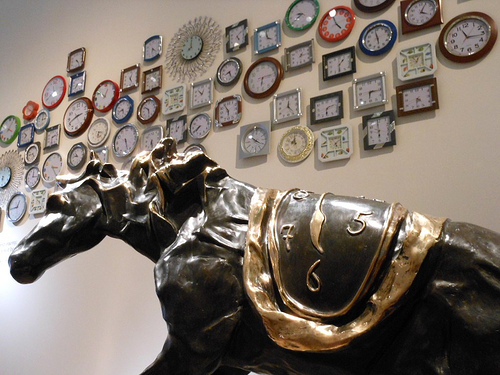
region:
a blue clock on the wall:
[355, 15, 396, 66]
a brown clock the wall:
[437, 5, 499, 79]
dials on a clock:
[67, 112, 84, 123]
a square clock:
[58, 41, 92, 73]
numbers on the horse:
[238, 165, 442, 315]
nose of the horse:
[3, 228, 51, 289]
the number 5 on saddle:
[336, 202, 382, 257]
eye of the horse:
[42, 178, 70, 222]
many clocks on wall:
[31, 21, 266, 158]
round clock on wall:
[228, 49, 290, 110]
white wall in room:
[401, 132, 473, 202]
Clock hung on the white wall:
[358, 108, 397, 149]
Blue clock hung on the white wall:
[360, 18, 395, 54]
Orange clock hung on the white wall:
[314, 7, 354, 40]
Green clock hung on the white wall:
[285, 0, 318, 30]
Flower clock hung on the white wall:
[20, 99, 37, 121]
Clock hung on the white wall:
[158, 16, 219, 82]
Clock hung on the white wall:
[188, 113, 210, 138]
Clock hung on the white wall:
[107, 120, 137, 157]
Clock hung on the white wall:
[440, 13, 497, 65]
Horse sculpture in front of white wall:
[8, 142, 498, 374]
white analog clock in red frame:
[40, 75, 67, 108]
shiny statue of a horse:
[7, 135, 499, 373]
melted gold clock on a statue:
[239, 183, 452, 358]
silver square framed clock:
[236, 118, 271, 158]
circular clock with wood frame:
[440, 9, 495, 65]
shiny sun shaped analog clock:
[163, 12, 221, 81]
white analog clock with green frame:
[1, 115, 20, 147]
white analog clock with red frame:
[90, 80, 120, 112]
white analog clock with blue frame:
[112, 94, 132, 123]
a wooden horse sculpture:
[2, 134, 493, 374]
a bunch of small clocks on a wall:
[0, 0, 485, 214]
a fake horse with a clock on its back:
[7, 134, 497, 372]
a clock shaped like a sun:
[163, 13, 224, 84]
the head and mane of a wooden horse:
[6, 135, 241, 285]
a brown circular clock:
[439, 8, 496, 69]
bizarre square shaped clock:
[392, 43, 446, 83]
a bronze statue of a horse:
[9, 140, 497, 372]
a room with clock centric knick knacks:
[2, 0, 499, 374]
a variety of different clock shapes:
[0, 1, 498, 215]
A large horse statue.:
[9, 132, 497, 373]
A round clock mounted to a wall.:
[434, 11, 498, 71]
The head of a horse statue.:
[4, 154, 150, 291]